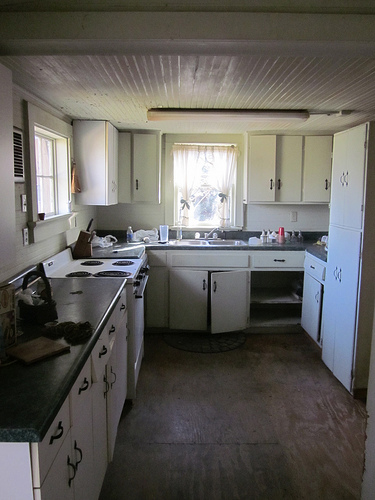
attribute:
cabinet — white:
[209, 269, 248, 335]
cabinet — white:
[168, 266, 209, 332]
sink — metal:
[172, 238, 247, 248]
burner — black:
[77, 257, 103, 267]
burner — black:
[111, 257, 134, 267]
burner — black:
[63, 270, 89, 278]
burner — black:
[92, 268, 131, 278]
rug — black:
[155, 334, 247, 359]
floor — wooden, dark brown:
[98, 327, 374, 498]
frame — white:
[159, 135, 241, 230]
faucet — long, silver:
[202, 225, 226, 239]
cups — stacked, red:
[278, 224, 287, 249]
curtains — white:
[178, 153, 234, 221]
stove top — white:
[42, 245, 142, 278]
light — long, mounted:
[142, 103, 312, 128]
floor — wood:
[200, 366, 324, 457]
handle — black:
[274, 254, 286, 265]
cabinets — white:
[243, 130, 341, 207]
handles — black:
[267, 177, 285, 192]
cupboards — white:
[243, 131, 304, 207]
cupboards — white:
[119, 129, 165, 205]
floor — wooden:
[122, 327, 353, 492]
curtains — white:
[179, 146, 229, 224]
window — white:
[35, 124, 65, 216]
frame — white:
[21, 97, 76, 141]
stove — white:
[39, 244, 147, 394]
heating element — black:
[64, 271, 130, 278]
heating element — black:
[79, 256, 135, 266]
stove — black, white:
[42, 244, 149, 406]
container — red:
[275, 225, 286, 245]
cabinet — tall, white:
[317, 119, 367, 397]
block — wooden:
[71, 229, 96, 258]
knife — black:
[83, 213, 96, 233]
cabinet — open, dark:
[249, 264, 305, 327]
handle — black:
[210, 280, 219, 293]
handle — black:
[201, 275, 207, 290]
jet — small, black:
[112, 256, 135, 271]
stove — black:
[66, 248, 151, 303]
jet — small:
[76, 254, 105, 268]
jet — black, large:
[89, 266, 127, 290]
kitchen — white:
[1, 78, 369, 455]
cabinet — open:
[160, 259, 267, 342]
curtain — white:
[166, 137, 254, 252]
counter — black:
[10, 277, 134, 439]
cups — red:
[275, 227, 285, 240]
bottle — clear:
[119, 218, 138, 248]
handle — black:
[63, 452, 80, 489]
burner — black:
[88, 266, 128, 283]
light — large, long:
[149, 104, 310, 127]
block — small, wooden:
[72, 227, 97, 261]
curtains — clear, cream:
[168, 138, 241, 232]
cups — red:
[273, 222, 287, 246]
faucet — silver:
[186, 227, 229, 249]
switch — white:
[16, 188, 30, 215]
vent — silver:
[10, 126, 32, 187]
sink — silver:
[174, 224, 229, 243]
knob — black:
[132, 274, 144, 291]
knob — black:
[136, 269, 148, 283]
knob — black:
[137, 261, 152, 280]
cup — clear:
[157, 220, 172, 245]